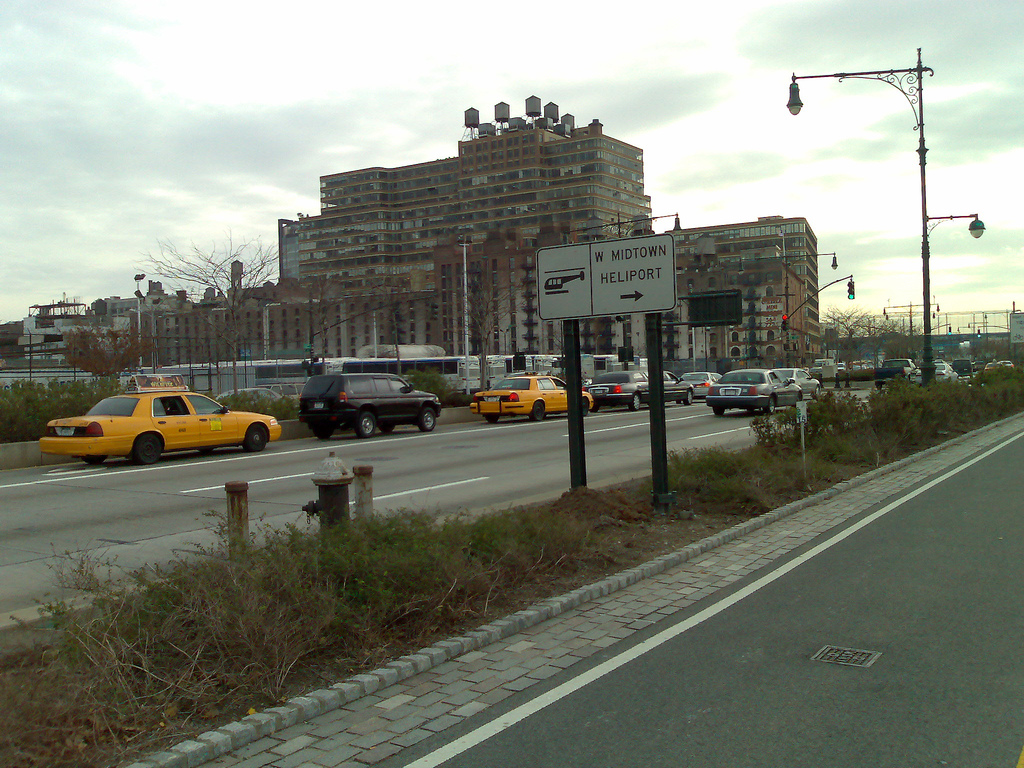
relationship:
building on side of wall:
[278, 125, 648, 266] [278, 125, 596, 266]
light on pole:
[920, 213, 987, 243] [910, 199, 937, 375]